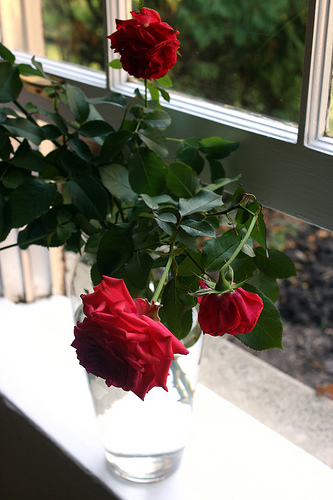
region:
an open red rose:
[106, 9, 177, 79]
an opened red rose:
[70, 277, 189, 396]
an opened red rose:
[190, 280, 265, 336]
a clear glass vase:
[70, 252, 203, 488]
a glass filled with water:
[70, 264, 203, 483]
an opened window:
[2, 1, 330, 229]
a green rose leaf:
[102, 164, 132, 198]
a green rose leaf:
[164, 163, 193, 194]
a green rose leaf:
[232, 287, 284, 353]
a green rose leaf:
[248, 243, 296, 279]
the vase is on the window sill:
[74, 227, 201, 483]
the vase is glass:
[71, 223, 214, 485]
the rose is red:
[67, 276, 189, 409]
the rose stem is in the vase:
[167, 358, 198, 409]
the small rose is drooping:
[183, 285, 266, 346]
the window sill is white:
[1, 299, 330, 499]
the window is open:
[229, 197, 328, 459]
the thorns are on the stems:
[156, 261, 171, 274]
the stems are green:
[149, 255, 171, 305]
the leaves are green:
[135, 134, 174, 160]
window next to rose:
[219, 23, 269, 69]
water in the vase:
[98, 413, 190, 489]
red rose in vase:
[85, 263, 200, 394]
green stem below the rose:
[149, 238, 191, 282]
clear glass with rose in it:
[110, 391, 201, 460]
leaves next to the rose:
[32, 143, 151, 207]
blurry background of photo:
[197, 19, 255, 63]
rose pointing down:
[193, 244, 285, 341]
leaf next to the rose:
[131, 143, 164, 185]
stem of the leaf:
[9, 101, 34, 117]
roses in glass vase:
[76, 242, 265, 479]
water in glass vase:
[89, 337, 206, 484]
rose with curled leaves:
[76, 285, 175, 395]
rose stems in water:
[167, 352, 196, 409]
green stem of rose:
[212, 219, 256, 279]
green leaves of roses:
[87, 138, 191, 217]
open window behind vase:
[230, 164, 327, 334]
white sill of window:
[178, 425, 256, 486]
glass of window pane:
[178, 5, 322, 145]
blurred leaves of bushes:
[202, 8, 274, 63]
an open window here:
[9, 4, 330, 464]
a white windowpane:
[0, 281, 329, 496]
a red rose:
[87, 7, 203, 89]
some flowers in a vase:
[41, 3, 293, 414]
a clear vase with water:
[60, 290, 221, 496]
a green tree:
[38, 0, 331, 139]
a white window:
[25, 5, 332, 240]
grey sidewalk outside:
[78, 251, 329, 439]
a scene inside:
[15, 25, 319, 498]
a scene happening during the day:
[10, 4, 324, 498]